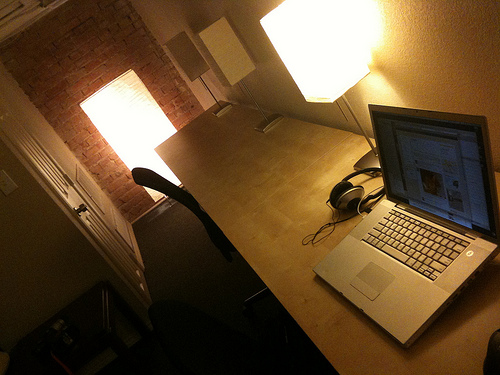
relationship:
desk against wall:
[153, 100, 500, 375] [153, 55, 474, 149]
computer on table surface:
[313, 104, 500, 349] [153, 97, 498, 374]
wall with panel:
[0, 3, 207, 211] [68, 57, 189, 200]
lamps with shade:
[262, 16, 379, 122] [255, 5, 381, 125]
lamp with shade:
[192, 17, 284, 133] [190, 14, 255, 86]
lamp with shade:
[162, 31, 231, 117] [157, 27, 207, 83]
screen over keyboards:
[369, 112, 495, 222] [368, 208, 456, 280]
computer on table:
[313, 104, 500, 349] [123, 100, 482, 374]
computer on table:
[313, 104, 500, 349] [154, 99, 499, 374]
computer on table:
[313, 104, 500, 349] [126, 105, 350, 282]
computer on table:
[313, 104, 500, 349] [154, 101, 374, 304]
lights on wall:
[255, 4, 387, 106] [191, 2, 498, 127]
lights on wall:
[255, 4, 387, 106] [11, 170, 134, 360]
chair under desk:
[129, 166, 237, 258] [153, 97, 483, 367]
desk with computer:
[153, 100, 500, 375] [313, 104, 500, 349]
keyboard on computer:
[304, 198, 499, 343] [313, 97, 497, 349]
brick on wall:
[103, 169, 129, 196] [0, 1, 202, 228]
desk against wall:
[153, 97, 483, 367] [180, 4, 498, 181]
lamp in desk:
[153, 29, 234, 124] [154, 85, 497, 374]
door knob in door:
[74, 200, 89, 217] [0, 100, 157, 320]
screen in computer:
[371, 112, 490, 231] [313, 104, 500, 349]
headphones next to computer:
[315, 162, 385, 228] [313, 97, 497, 349]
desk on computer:
[153, 97, 483, 367] [313, 97, 497, 349]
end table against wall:
[6, 280, 156, 373] [2, 156, 151, 349]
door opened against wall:
[0, 100, 157, 320] [2, 142, 150, 362]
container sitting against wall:
[45, 312, 74, 349] [0, 136, 146, 372]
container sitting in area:
[45, 312, 74, 349] [0, 281, 155, 371]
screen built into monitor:
[371, 112, 490, 231] [366, 101, 485, 237]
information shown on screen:
[375, 117, 485, 225] [371, 112, 490, 231]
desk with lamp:
[153, 100, 500, 375] [261, 4, 370, 106]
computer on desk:
[313, 104, 500, 349] [153, 97, 483, 367]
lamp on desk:
[206, 21, 246, 83] [153, 100, 500, 375]